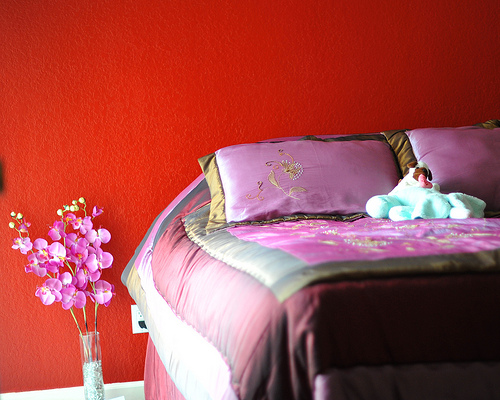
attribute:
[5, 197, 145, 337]
flowers — purple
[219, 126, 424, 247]
pillow — purple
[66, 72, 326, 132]
wall — red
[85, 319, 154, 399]
vase — small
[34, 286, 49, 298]
flower pedal — small, purple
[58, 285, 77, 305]
flower pedal — purple, small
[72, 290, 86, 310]
flower pedal — small, purple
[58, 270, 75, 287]
flower pedal — purple, small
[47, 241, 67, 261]
flower pedal — small, purple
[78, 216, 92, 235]
flower pedal — purple, small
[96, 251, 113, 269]
flower pedal — small, purple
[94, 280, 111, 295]
flower pedal — purple, small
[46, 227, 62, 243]
flower pedal — small, purple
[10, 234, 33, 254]
flower — pink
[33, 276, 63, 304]
flower — pink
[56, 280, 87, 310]
flower — pink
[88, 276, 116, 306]
flower — pink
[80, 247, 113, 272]
flower — pink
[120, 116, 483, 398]
bed — made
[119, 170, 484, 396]
blanket — pink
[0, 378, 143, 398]
wainscoting — white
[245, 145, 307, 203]
decoration — white, gold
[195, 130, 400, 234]
pillow — pink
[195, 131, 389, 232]
border — gold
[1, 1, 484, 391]
wall — painted, red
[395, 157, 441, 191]
plush toy — small, dog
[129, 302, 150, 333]
outlet — white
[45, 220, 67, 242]
flower — purple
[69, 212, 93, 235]
flower — purple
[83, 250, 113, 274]
flower — purple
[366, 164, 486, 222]
toy — blue, plush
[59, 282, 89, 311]
flower — purple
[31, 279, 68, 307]
flower — purple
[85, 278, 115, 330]
flower — purple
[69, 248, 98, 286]
flower — purple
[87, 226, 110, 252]
flower — purple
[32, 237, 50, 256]
flower — purple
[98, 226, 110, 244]
petal — purple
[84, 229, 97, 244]
petal — purple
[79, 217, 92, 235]
petal — purple